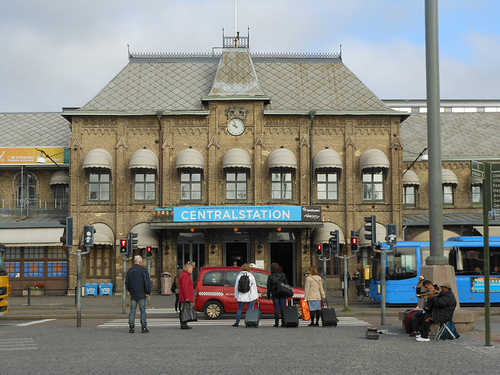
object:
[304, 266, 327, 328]
person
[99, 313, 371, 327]
crosswalk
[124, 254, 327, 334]
5 people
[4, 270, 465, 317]
street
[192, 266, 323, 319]
van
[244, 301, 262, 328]
suitcase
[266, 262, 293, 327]
woman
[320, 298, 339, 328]
suitcase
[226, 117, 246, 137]
clock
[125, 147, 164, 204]
window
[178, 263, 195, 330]
pedestrians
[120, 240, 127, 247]
light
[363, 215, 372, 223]
light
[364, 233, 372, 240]
light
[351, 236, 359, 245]
light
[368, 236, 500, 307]
bus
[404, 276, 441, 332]
people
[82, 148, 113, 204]
windows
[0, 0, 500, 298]
building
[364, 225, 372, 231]
light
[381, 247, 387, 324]
pole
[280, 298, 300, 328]
suitcase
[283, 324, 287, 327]
wheels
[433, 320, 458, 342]
chairs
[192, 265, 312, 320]
car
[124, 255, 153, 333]
man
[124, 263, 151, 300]
jacket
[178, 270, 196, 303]
jacket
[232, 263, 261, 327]
person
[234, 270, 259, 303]
jacket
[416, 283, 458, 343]
man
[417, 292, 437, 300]
instrument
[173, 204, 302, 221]
sign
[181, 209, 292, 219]
central station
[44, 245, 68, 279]
windows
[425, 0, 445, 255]
pole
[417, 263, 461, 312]
cement block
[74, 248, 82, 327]
light post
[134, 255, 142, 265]
hair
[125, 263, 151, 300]
shirt